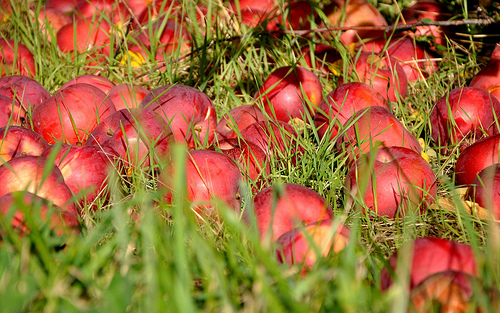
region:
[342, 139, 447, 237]
red apples in a field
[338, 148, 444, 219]
apples have been harvested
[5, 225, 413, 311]
the grass is long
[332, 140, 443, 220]
the apples are on the ground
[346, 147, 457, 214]
the apples have been picked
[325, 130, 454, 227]
several apples are laying around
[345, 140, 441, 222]
apples are red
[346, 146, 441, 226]
apples in a field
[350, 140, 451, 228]
the apples are ripe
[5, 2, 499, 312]
apples in the grass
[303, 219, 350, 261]
yellow spot on red apple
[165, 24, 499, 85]
shadows on the grass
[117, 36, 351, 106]
apples with yellow spots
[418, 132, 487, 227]
yellow leaves in the grass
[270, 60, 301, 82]
shadow on an apple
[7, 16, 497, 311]
red apples scattered in the grass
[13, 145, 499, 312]
blades of grass in the foreground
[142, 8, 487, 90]
twig in the grass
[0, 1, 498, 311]
Apples on the ground.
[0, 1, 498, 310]
Grass covering the ground.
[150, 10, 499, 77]
Stick on the ground.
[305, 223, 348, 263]
Yellow color on the apple.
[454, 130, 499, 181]
Red color on the apple.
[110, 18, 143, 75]
Yellow flower in the grass.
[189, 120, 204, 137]
Brown stem on the apple.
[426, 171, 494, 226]
Brown leaf on the ground.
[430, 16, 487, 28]
Bark on the stick.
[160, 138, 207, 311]
Green blade of grass.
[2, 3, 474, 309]
apples laying on the ground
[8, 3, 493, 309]
apples scattered in the grass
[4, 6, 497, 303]
red apples laying in the sun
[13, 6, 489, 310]
long blades of green grass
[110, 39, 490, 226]
yellow leaves in the grass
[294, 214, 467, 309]
apples with yellow spots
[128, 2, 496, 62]
small branch laying on the apples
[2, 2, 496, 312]
sunny day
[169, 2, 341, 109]
shadow on the grass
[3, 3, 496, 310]
red apples strewn on the ground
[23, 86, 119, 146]
red apple laying in grass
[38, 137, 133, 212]
red apple laying in grass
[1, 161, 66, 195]
red apple laying in grass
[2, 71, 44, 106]
red apple laying in grass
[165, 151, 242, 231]
red apple laying in grass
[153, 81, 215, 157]
red apple laying in grass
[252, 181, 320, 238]
red apple laying in grass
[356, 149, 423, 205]
red apple laying in grass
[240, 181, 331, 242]
Red apple on the floor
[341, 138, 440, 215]
Red apple on the floor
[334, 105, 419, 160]
Red apple on the floor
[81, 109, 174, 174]
Red apple on the floor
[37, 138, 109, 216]
Red apple on the floor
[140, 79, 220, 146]
Red apple on the floor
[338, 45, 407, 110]
Red apple on the floor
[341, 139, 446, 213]
Apple on the ground in the field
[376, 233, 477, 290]
Apple on the ground in the field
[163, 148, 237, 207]
Apple on the ground in the field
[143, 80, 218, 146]
Apple on the ground in the field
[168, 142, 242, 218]
Red Apple on the ground in field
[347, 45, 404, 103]
Red Apple on the ground in field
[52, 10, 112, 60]
Red Apple on the ground in field